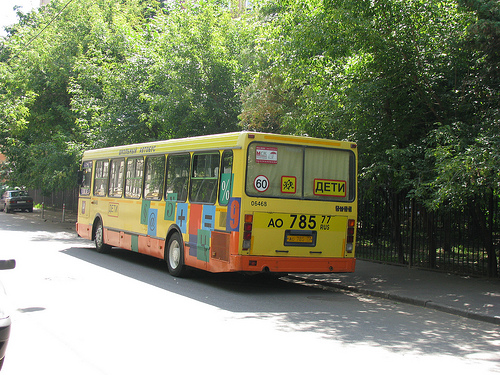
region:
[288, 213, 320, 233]
"785" on back of bus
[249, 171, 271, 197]
"60" in a circle on back of bus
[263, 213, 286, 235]
"AO" on back of bus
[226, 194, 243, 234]
red "9" on blue background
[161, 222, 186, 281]
rear driver's side tire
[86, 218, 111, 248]
front driver's side tire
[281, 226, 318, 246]
license plate on back of bus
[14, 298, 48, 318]
rectangular shadow on ground on left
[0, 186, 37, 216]
car parked on street in front of bus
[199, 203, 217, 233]
black equal sign on blue background on side of bus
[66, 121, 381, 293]
the bus is yellow & orange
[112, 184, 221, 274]
it has blue, green & red signs on the side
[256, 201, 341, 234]
AO 785 77 RUS appears on the back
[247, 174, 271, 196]
the number 60 is inside a red/white circle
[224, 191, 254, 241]
the number 9 is in orange inside a purple box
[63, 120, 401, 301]
the bus is stopped at the curb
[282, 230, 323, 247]
the license plate is yellow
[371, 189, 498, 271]
an iron fence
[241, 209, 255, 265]
the back lights are four high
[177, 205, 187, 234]
the plus sign is black in a blue box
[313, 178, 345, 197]
A sign on a bus using Cyrillic letters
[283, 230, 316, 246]
A license plate on a bus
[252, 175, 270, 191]
A sign on a bus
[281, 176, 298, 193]
A sign on a bus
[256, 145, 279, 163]
A sign on a bus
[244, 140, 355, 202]
A window on a bus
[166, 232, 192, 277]
A wheel on a bus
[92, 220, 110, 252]
A wheel on a bus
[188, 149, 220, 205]
A window on a bus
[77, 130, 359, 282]
A yellow bus.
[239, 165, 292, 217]
the number 60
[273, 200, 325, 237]
the number 785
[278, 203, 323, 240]
the number 785 on a bus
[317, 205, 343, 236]
the number 77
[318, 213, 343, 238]
the number 77 on a bus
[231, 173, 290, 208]
the number 60 on a bus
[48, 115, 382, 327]
a yellow bus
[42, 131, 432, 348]
a bus parked on the side of a road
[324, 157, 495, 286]
a black fence alongside a sidewalk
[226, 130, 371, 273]
stickers on a bus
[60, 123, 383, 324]
a yellow bus on the street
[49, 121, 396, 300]
a parked yellow bus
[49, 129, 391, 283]
A yellow bus with colored signs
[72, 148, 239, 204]
Windows on a bus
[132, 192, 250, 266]
colored signs on a bus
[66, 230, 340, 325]
Shadow of a bus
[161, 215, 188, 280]
a tire on a bus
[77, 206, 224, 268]
Two tires on a bus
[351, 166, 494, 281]
a fence near a sidewalk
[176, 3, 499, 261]
Trees behind a fence